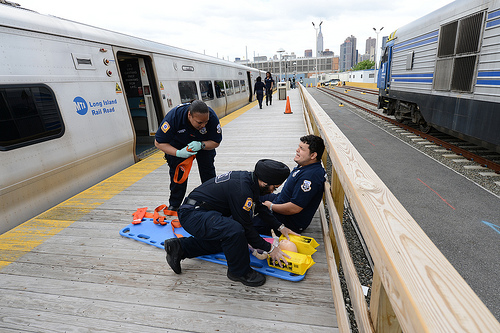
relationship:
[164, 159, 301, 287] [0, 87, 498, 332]
emergency worker kneeling on ground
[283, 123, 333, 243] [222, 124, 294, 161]
hurt man on ground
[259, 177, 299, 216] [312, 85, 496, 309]
tie on track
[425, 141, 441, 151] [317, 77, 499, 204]
cross tie on track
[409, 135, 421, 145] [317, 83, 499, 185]
tie on track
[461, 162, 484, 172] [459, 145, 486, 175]
tie on track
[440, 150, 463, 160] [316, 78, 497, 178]
tie on track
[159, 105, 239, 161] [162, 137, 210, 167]
person wearing blue gloves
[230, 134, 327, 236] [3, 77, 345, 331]
hurt man on ground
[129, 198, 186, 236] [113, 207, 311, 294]
straps on board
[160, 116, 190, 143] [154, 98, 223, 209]
uniform on woman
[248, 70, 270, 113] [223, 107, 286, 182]
lady on platform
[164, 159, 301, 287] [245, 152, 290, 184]
emergency worker wearing turban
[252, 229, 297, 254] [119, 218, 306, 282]
doll baby on backboard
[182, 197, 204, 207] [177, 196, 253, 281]
belt on pants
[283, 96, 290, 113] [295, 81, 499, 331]
cone next to rail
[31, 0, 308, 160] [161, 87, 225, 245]
train next to person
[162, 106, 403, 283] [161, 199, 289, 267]
man wearing pants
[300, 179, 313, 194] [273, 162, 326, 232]
patch on shirt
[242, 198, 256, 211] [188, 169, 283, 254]
patch on shirt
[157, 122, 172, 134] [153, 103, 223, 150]
patch on shirt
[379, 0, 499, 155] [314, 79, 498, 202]
train on tracks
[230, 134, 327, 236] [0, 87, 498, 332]
hurt man on ground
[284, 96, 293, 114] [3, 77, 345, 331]
cone on ground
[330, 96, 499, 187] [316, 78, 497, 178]
tie on track